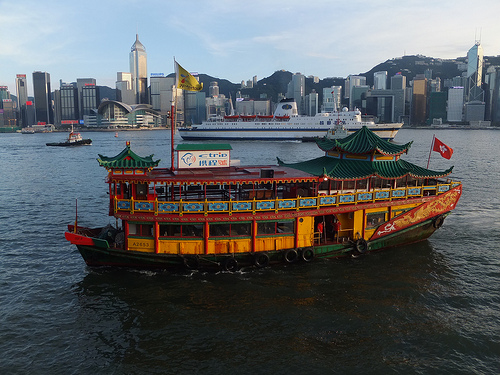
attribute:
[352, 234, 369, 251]
tire — black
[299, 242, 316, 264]
tire — black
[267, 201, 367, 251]
door — yellow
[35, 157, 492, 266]
boat — floating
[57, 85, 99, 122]
building — tall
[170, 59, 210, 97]
flag — yellow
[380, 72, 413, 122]
building — tall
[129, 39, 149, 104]
building — tall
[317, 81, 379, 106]
building — tall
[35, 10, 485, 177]
building — tall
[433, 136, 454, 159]
flag — red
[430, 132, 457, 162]
flag — red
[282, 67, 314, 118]
building — tall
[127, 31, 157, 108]
building — tall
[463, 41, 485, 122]
building — tall